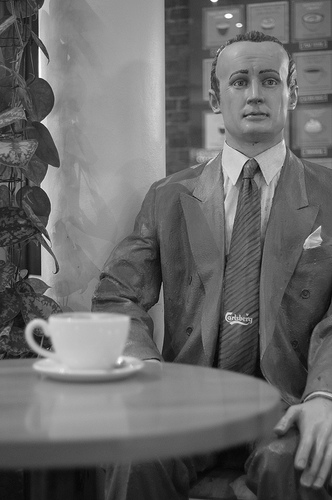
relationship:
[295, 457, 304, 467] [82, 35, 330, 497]
fingernail of statue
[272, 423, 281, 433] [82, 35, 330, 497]
fingernail of statue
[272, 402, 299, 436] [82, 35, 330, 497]
finger of statue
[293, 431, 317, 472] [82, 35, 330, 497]
finger of statue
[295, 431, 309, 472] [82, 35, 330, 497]
finger of statue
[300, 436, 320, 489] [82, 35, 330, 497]
finger of statue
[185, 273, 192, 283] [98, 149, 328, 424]
button on jacket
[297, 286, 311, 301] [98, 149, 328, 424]
button on jacket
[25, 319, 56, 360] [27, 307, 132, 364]
handle on cup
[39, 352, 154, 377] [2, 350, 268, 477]
plate on table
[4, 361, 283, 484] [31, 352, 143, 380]
table below plate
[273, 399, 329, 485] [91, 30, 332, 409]
hand of man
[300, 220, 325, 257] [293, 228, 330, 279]
napkin in pocket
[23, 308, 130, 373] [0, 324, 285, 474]
cup on table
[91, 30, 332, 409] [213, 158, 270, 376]
man wearing a tie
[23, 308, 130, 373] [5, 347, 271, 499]
cup on table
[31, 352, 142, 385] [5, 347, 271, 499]
plate on table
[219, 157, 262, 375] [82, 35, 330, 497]
tie on statue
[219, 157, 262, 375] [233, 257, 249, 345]
tie has stripes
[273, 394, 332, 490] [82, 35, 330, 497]
hand on statue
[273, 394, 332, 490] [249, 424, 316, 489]
hand on knee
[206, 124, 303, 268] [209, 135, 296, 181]
shirt has collar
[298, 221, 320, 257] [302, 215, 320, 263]
pocket has paper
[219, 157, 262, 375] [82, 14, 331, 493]
tie of man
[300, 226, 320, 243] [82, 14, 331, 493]
handkerchief of man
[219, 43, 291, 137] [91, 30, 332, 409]
face of man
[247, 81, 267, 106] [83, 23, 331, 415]
nose of man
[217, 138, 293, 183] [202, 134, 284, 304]
collar of shirt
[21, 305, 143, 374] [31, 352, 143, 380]
cup on plate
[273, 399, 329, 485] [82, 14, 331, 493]
hand on man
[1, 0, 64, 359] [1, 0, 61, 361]
leaves on leaves